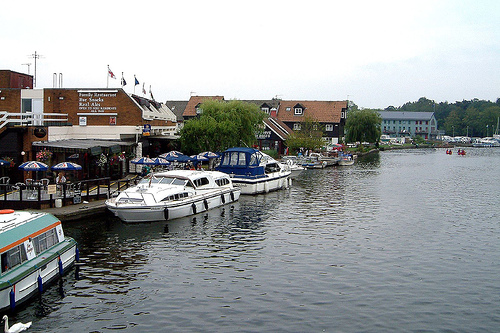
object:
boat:
[104, 169, 240, 222]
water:
[0, 146, 500, 333]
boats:
[213, 146, 292, 195]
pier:
[0, 131, 500, 222]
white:
[177, 210, 188, 215]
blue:
[214, 146, 268, 179]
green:
[0, 213, 60, 251]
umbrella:
[51, 161, 82, 170]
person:
[55, 172, 67, 184]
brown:
[125, 102, 133, 114]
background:
[273, 104, 347, 137]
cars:
[454, 136, 471, 144]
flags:
[108, 66, 117, 79]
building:
[0, 87, 178, 187]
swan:
[1, 315, 33, 333]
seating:
[25, 178, 49, 199]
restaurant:
[78, 93, 117, 113]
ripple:
[350, 180, 378, 204]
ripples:
[177, 255, 242, 293]